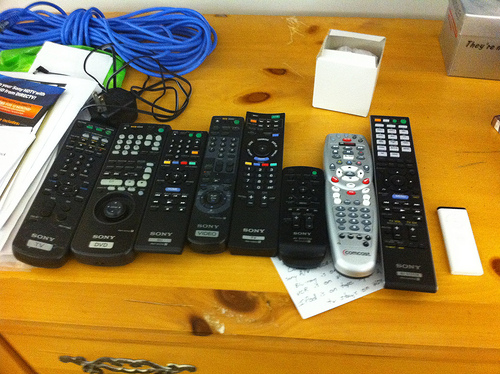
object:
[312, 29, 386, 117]
box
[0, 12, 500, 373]
table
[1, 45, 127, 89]
green bag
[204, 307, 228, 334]
paint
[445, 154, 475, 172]
ground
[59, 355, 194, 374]
handle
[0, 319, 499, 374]
drawer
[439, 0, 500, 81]
side box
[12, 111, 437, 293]
control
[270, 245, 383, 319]
card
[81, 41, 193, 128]
charger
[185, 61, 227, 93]
ground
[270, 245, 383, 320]
paper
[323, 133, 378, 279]
comcast remote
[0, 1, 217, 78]
blue wires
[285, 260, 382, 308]
note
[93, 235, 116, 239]
sony